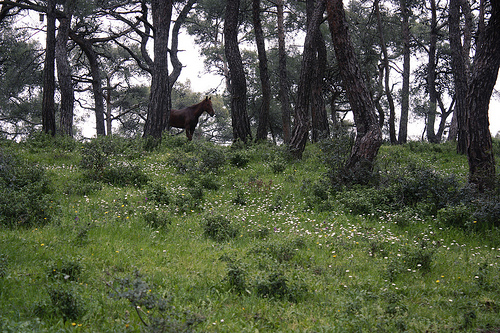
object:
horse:
[166, 94, 216, 142]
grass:
[1, 132, 499, 332]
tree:
[108, 1, 197, 148]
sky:
[0, 2, 499, 150]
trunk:
[462, 3, 499, 189]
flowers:
[434, 275, 463, 287]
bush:
[0, 150, 59, 231]